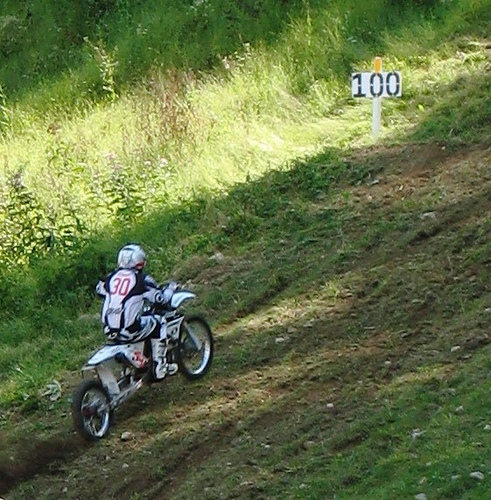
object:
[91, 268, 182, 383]
outfit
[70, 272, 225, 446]
dirtbike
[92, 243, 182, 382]
person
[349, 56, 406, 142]
sign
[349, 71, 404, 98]
100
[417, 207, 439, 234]
stones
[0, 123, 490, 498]
field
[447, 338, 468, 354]
stones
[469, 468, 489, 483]
stones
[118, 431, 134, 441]
stones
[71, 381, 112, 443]
tires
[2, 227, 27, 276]
plants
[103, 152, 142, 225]
plants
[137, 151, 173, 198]
plants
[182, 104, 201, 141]
plants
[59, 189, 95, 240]
plants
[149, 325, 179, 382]
boot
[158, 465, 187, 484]
dirt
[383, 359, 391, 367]
rocks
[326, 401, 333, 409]
dirt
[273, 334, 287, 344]
rocks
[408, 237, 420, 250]
dirt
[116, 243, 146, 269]
helmet color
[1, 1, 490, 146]
field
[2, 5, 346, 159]
grass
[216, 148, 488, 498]
ground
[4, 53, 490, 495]
track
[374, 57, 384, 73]
yellow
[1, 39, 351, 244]
sunshine rays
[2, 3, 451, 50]
shadows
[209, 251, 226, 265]
rocks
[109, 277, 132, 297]
number 30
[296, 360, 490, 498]
grass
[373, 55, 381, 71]
yellow reflector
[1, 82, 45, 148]
tall weeds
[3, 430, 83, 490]
dirt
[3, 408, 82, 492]
air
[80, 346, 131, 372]
motorcycle fender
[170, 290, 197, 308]
motorcycle fender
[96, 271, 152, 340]
person's back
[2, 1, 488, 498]
hill